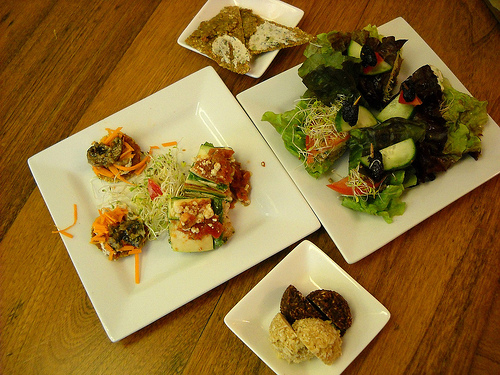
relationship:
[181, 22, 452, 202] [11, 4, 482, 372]
food on plates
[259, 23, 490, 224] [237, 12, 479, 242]
food on plate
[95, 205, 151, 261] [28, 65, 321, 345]
salad on plate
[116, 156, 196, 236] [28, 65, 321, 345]
salad on plate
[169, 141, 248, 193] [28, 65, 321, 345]
food on plate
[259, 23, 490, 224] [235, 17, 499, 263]
food on plate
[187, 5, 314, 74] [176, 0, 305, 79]
bread on plate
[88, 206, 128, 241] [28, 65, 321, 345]
carrot on plate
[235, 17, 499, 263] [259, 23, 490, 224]
plate with food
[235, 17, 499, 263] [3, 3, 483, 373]
plate on table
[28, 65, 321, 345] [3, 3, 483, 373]
plate on table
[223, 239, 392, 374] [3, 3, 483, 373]
plate on table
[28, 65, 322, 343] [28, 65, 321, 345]
sprouts on plate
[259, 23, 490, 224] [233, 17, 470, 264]
food on plate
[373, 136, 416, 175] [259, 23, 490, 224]
cucumber on food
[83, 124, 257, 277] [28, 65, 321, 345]
sandwiches on plate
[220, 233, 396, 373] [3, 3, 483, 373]
plate on table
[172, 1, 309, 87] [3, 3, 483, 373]
plate on table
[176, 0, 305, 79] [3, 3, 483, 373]
plate on table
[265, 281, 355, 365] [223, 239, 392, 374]
cookies on plate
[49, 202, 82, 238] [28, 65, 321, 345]
slice on plate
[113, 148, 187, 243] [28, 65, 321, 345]
lettuce on plate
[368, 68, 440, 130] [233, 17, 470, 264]
sandwich on plate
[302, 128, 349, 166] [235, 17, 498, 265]
tomato on plate